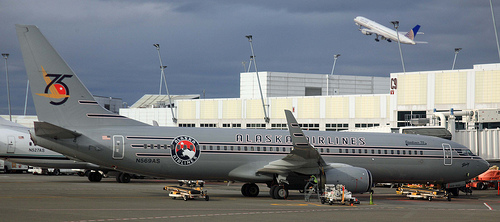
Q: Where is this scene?
A: Airport.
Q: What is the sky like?
A: Overcast.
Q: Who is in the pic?
A: Employee.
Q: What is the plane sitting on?
A: Tarmac.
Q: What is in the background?
A: Building.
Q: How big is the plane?
A: Very big.